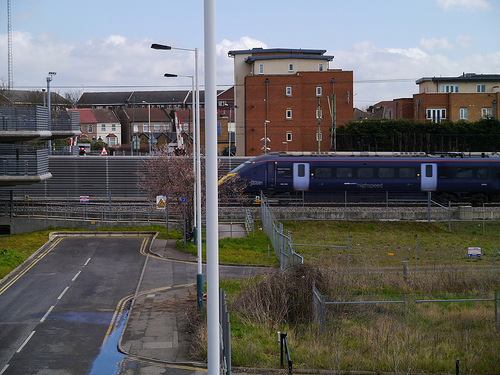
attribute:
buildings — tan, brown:
[367, 70, 499, 124]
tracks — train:
[15, 199, 495, 209]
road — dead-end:
[45, 202, 182, 364]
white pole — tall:
[204, 5, 217, 374]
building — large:
[241, 32, 446, 200]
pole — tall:
[192, 3, 230, 373]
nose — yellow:
[200, 163, 252, 205]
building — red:
[243, 70, 355, 154]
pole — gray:
[263, 74, 270, 152]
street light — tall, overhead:
[149, 41, 204, 312]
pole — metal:
[201, 0, 220, 375]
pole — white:
[203, 0, 221, 375]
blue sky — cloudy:
[4, 0, 499, 105]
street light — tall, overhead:
[162, 67, 197, 258]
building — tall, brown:
[201, 42, 394, 223]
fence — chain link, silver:
[256, 190, 498, 344]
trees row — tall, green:
[334, 115, 498, 150]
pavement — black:
[30, 219, 160, 362]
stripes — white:
[78, 252, 95, 269]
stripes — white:
[66, 267, 88, 284]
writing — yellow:
[344, 181, 384, 191]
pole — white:
[193, 2, 233, 372]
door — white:
[292, 159, 313, 199]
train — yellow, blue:
[216, 148, 484, 203]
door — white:
[287, 160, 313, 195]